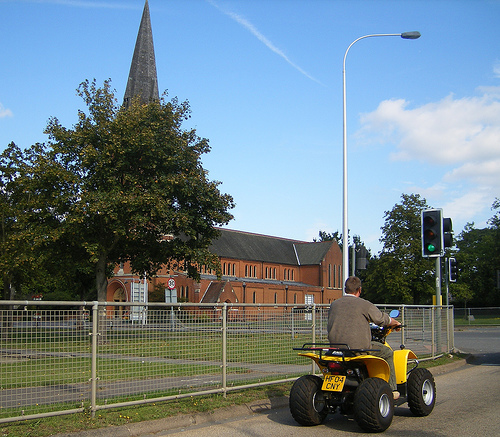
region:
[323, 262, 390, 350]
this is a man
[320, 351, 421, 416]
this is a quad bike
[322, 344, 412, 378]
the quad bike is yellow in color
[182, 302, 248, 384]
this is a fence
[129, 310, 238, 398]
the fence is metallic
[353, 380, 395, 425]
this is the wheel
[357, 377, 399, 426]
the wheel is black in color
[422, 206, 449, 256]
this is the traffic light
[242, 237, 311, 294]
this is a building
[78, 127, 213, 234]
these are the leaves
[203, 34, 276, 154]
this is the sky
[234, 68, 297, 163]
the sky is blue in color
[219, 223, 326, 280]
this is a buidling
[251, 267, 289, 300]
this is the wall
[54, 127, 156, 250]
this is a tree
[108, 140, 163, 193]
the leaves are green in color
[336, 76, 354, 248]
this is a pole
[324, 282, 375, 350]
this is a man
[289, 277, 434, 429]
man riding a small tractor into town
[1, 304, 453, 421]
a metal fence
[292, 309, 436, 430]
a yellow small tractor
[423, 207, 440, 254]
a streetlight set on green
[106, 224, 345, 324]
a church made of bricks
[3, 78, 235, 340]
a green tree in a park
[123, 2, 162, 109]
a church tower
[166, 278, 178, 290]
a round street sign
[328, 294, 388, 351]
man wearing a light brown sweater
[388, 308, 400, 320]
a mirror on a tractor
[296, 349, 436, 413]
yellow tractor with big wheels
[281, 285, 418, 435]
man riding on tractor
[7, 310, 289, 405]
long wire fence seperating grounds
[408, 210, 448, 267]
traffic light on the corner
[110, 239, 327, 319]
large church building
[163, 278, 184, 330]
signs by the road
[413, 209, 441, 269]
traffic light is green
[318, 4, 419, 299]
tall light post on the corner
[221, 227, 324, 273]
black roof on the church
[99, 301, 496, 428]
A black paved road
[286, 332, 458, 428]
The yellow vehicle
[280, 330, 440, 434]
A yellow vehicle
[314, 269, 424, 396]
The man on the vehicle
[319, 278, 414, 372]
A man on the vehicle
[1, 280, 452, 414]
A gray fence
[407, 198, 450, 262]
The black traffic light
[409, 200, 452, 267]
A black traffic light on the pole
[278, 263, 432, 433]
man riding a ATV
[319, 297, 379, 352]
man wearing a gray shirt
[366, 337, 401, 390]
man wearing gray pants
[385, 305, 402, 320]
mirror on the ATV